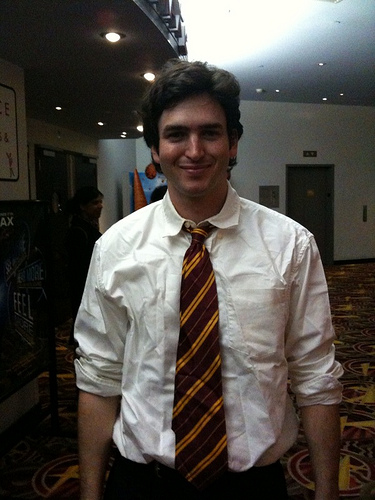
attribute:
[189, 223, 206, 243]
stipe — yellow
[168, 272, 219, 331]
stripe — yellow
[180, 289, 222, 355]
stripe — yellow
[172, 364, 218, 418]
stripe — yellow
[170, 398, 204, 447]
stripe — yellow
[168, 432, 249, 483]
stripe — yellow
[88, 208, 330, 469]
shirt — white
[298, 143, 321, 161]
sign — black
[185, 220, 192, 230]
button — white, small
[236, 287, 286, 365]
pocket — white, large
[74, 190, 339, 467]
shirt — white, wrinkled, long sleeve, button down, rumpled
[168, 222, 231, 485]
tie — long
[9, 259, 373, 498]
rug — multi-colored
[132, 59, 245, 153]
hair — dark colored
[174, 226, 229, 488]
tie — maroon, yellow, striped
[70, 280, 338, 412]
sleeves — long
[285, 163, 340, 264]
elevator door — grey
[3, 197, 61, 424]
stand — metal, black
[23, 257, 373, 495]
carpet — patterned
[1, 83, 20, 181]
sign — black, white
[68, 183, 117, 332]
woman — dark haired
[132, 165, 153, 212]
cone — orange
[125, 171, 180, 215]
advertisement — 3d